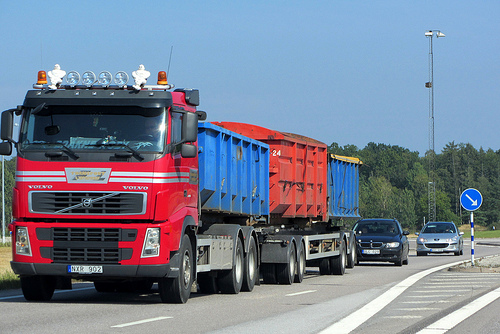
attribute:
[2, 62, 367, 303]
truck — blue, red, long, large, steel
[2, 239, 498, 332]
road — asphalt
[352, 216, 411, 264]
car — driving, black, dark blue, diving, silver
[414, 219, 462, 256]
car — driving, silver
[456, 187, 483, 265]
pole — striped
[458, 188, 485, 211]
sign — white, blue, directional, round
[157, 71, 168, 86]
light — orange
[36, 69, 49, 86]
light — orange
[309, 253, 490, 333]
line — white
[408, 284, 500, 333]
line — white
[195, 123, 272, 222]
cargo — blue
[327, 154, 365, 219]
cargo — blue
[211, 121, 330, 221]
cargo — red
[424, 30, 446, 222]
tower — metal, tall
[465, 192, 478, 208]
arrow — horizontally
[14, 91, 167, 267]
front — red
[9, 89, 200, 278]
section — red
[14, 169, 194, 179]
stripe — silver, gray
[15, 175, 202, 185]
stripe — silver, gray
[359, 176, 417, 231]
tree — green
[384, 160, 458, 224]
tree — green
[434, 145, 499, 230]
tree — green